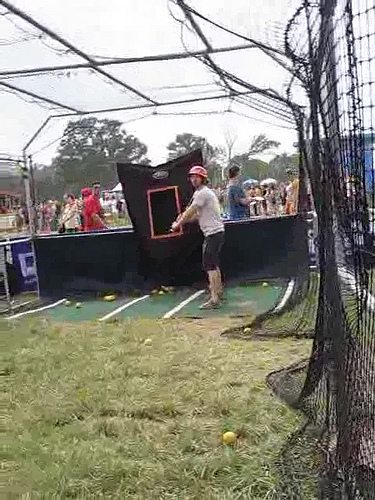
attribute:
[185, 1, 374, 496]
mesh — black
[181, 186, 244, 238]
shirt — white, short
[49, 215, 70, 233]
purse — black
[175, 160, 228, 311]
man — standing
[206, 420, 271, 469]
ball — yellow